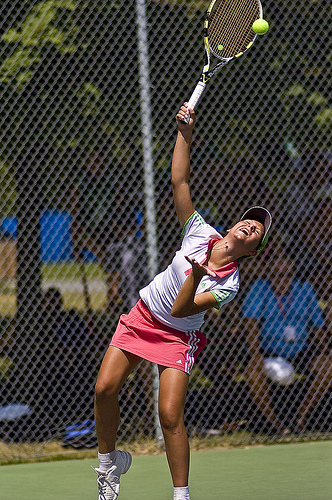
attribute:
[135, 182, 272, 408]
woman — white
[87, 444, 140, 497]
shoe — tennis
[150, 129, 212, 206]
arm — on woman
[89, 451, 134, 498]
shoes — white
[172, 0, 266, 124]
racket — woman's, black, yellow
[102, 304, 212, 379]
skirt — pink, white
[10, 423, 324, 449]
fence — chain link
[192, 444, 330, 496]
tennis court — pictured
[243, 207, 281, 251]
cap — green, grey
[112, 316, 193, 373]
skirt — pink, white, woman's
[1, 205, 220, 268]
wall — blue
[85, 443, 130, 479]
shoes — white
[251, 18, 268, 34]
tennis ball — green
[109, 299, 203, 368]
skirt — white, pink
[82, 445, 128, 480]
sock — white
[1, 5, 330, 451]
fence — silver, chain link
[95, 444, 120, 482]
socks — white